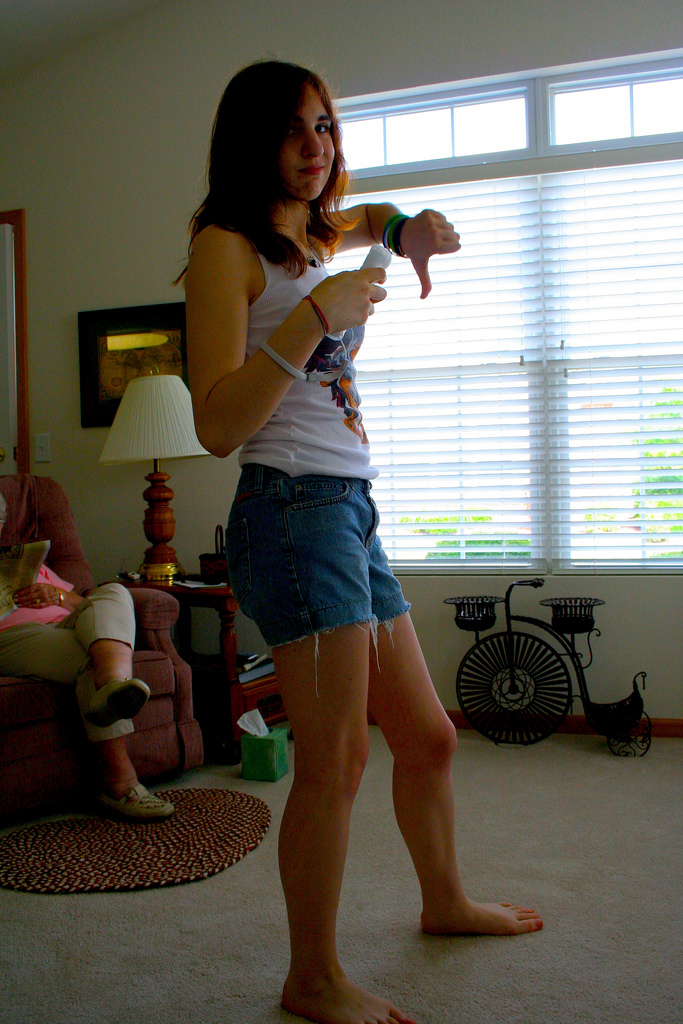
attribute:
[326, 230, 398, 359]
wii remote — white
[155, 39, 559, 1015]
woman — bare feet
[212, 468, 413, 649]
jean — shorts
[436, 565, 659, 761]
tricycle — decor, black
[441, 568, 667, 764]
bicycle — vintage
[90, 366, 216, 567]
lamp — wooden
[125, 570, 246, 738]
table — wooden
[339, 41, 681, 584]
blinds — white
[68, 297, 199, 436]
artwork — framed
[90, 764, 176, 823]
foot — woven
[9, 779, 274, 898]
rug — red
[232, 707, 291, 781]
tissue box — green, white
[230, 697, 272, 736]
tissue — white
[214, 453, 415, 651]
shorts — denim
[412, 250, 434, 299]
thumb — pointing down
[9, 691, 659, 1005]
carpet — white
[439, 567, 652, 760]
cart — black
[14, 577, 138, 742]
pants — beige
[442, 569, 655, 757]
planter — bicycle, shaped